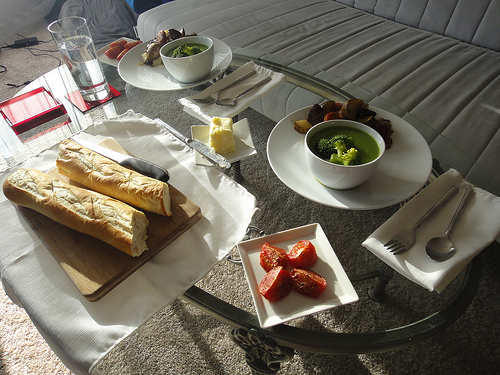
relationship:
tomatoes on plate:
[258, 241, 328, 302] [239, 222, 359, 328]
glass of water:
[33, 6, 130, 101] [65, 45, 115, 87]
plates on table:
[115, 25, 437, 213] [146, 57, 401, 295]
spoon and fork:
[418, 184, 480, 263] [382, 180, 462, 256]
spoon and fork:
[212, 73, 278, 104] [190, 60, 260, 107]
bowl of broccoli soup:
[304, 115, 390, 185] [309, 128, 376, 165]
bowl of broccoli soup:
[152, 29, 216, 77] [163, 39, 205, 57]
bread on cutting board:
[22, 134, 192, 278] [16, 139, 202, 301]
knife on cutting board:
[67, 131, 169, 182] [16, 139, 202, 301]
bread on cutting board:
[51, 135, 176, 219] [16, 139, 202, 301]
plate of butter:
[178, 120, 258, 164] [208, 117, 237, 153]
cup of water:
[58, 20, 138, 105] [57, 31, 108, 101]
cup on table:
[58, 20, 138, 105] [146, 57, 401, 295]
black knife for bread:
[70, 132, 171, 183] [22, 134, 192, 278]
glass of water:
[42, 12, 110, 105] [57, 31, 108, 101]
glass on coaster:
[42, 12, 110, 105] [60, 85, 128, 110]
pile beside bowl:
[299, 98, 397, 131] [304, 115, 390, 185]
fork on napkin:
[382, 220, 424, 271] [391, 200, 422, 225]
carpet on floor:
[100, 305, 238, 373] [1, 0, 481, 371]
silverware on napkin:
[193, 70, 256, 104] [176, 59, 285, 125]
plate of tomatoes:
[239, 222, 359, 328] [258, 241, 328, 302]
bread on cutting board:
[3, 145, 171, 260] [16, 139, 202, 301]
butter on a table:
[208, 117, 237, 153] [146, 57, 401, 295]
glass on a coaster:
[46, 15, 111, 104] [60, 85, 128, 110]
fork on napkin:
[382, 180, 462, 256] [361, 167, 498, 294]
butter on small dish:
[201, 104, 242, 166] [182, 104, 262, 168]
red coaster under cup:
[5, 86, 80, 152] [38, 16, 137, 106]